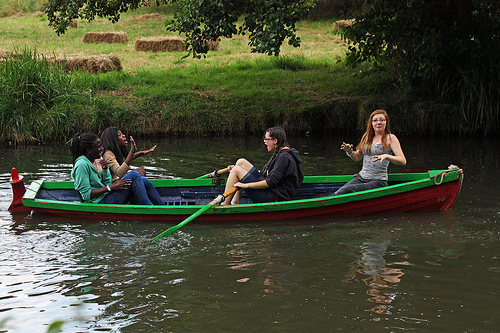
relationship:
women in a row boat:
[72, 110, 407, 205] [7, 166, 465, 224]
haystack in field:
[40, 56, 119, 74] [0, 0, 394, 72]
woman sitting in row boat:
[219, 126, 302, 202] [7, 166, 465, 224]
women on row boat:
[330, 109, 407, 196] [7, 166, 465, 224]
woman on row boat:
[71, 134, 149, 203] [7, 166, 465, 224]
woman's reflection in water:
[350, 238, 407, 321] [0, 133, 500, 332]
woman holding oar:
[219, 126, 302, 202] [152, 185, 240, 242]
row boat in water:
[7, 166, 465, 224] [0, 133, 500, 332]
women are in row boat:
[72, 110, 407, 205] [7, 166, 465, 224]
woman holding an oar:
[219, 126, 302, 202] [192, 165, 231, 177]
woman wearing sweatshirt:
[71, 134, 149, 203] [71, 156, 110, 203]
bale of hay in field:
[134, 38, 189, 55] [0, 0, 394, 72]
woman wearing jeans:
[71, 134, 149, 203] [101, 173, 163, 202]